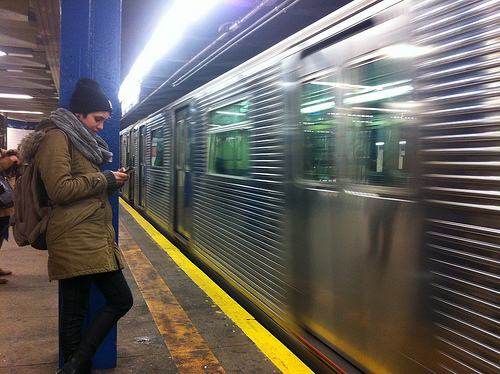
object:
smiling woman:
[8, 77, 136, 374]